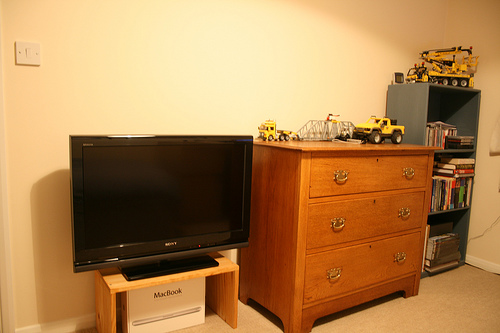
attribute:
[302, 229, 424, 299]
drawer — wooden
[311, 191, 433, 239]
drawer — wooden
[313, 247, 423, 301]
drawer — wooden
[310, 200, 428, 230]
drawer — wooden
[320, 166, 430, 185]
drawer — wooden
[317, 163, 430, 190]
drawer — wooden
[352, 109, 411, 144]
trucks — toy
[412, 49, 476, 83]
truck — yellow, model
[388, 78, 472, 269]
bookshelf — tall, gray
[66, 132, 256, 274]
television — large, black, flatscreen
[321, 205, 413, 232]
handles — decorative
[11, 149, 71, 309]
shadow — television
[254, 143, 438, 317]
furniture — polished, wooden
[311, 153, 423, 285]
drawers — wooden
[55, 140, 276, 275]
tv — flat screen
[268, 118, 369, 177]
bridge — white, model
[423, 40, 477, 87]
truck — monster, yellow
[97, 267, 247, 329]
stand — wood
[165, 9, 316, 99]
walls — white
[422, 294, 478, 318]
carpet — cream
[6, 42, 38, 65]
board — switch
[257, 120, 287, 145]
truck — toy, yellow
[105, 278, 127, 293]
table — wooden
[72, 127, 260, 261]
television — color, black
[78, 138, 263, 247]
tv — flat, screen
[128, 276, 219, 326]
box — macbook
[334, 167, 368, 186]
handles — drawer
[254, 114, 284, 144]
truck — toy, yellow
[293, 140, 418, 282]
chest — wooden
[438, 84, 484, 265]
bookcase — grey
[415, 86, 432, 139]
shelf — book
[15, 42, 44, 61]
plate — white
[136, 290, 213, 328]
laptop — silver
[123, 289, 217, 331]
box — macbook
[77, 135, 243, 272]
tv — screen, flat, black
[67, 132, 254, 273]
tv — black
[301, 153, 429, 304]
drawers — brown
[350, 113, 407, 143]
toy truck — yellow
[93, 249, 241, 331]
tv stand — tan colored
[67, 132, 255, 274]
tv set — black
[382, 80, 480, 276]
book shelf — gray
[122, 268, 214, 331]
box — white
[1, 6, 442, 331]
wall — white